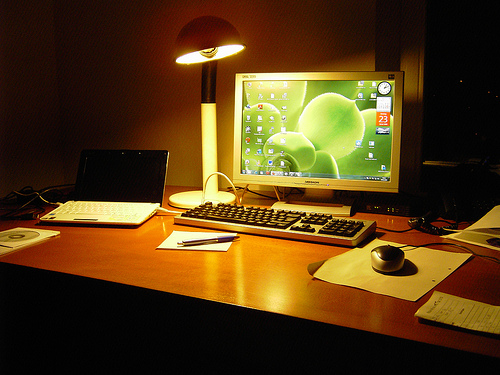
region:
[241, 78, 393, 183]
Green colored desktop background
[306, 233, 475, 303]
Computer mouse on top of a sheet of paper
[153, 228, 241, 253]
A pen on top of a piece of paper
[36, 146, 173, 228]
Laptop computer on a desk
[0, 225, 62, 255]
CD disk on top of a desk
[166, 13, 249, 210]
Lamp light shining down on a keyboard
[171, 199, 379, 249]
Keyboard on top of the desk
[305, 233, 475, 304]
paper substitute as a mousepad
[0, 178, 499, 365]
brown desk with many items on top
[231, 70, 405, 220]
computer monitor on a desk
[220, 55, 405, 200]
this is a computer screen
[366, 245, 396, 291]
this is a computer mouse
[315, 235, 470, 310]
this is a mouse pad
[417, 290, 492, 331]
this is a note book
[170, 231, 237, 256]
this is a ped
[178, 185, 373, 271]
this is a computer keyboard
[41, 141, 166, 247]
this is a lap top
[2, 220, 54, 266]
this is a compact disk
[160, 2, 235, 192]
this is a lamp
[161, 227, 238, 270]
a white note book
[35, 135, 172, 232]
This is a laptop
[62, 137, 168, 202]
This is a laptop screen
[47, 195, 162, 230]
This is a laptop keyboard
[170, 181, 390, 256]
This is a keyboard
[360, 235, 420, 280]
This is a mouse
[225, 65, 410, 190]
This is a monitor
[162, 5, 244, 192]
This is a study lamp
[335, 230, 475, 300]
This is a mouse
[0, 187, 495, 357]
This is a table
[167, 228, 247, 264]
This is a pen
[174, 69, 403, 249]
Computer sitting on an office desk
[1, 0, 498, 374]
Dimly lit office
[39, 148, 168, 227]
Small open laptop sitting on a desk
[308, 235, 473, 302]
Computer mouse placed on a piece of paper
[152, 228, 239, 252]
Pen and pad of paper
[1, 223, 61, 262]
Compact disc in a white case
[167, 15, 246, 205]
Metal desk lamp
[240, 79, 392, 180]
Green computer screen wallpaper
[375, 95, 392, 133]
Calender application on computers desktop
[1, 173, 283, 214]
Black and white electrical wires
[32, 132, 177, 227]
black and white laptop sitting on table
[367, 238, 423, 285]
black and grey computer mouse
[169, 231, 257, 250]
ink pen laying on desk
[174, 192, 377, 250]
grey and black computer keyboard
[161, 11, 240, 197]
metal lamp on desk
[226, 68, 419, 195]
flat screen computer monitor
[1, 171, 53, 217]
pile of electric computer cords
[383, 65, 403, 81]
logo on front of computer monitor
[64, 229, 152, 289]
brown wooden desk top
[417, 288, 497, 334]
piece of paper laying on desk